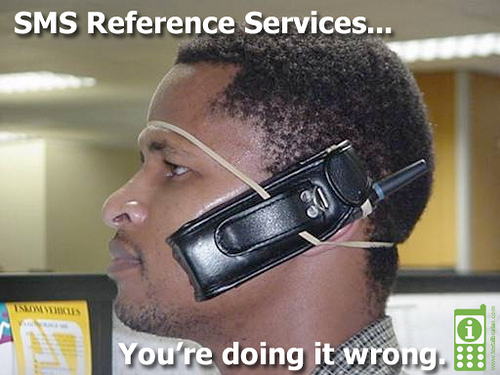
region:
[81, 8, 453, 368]
man has a cell phone on his head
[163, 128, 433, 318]
cell phone is color black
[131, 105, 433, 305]
cell phone hold by an elastic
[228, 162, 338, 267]
elastic over a phone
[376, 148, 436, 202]
antenna of phone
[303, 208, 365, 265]
an ear behind a phone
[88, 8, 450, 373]
man wears a squared shirt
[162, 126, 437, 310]
cell phone is in a case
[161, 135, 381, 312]
case of phone is black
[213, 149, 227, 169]
a rubber band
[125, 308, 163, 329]
hair on the mans face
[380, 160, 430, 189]
an antenna to the cellphone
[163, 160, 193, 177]
the mans left eye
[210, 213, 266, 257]
clip on the cellphone case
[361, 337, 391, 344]
the man is wearing a collar shirt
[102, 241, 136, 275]
the mans lips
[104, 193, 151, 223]
the mans nose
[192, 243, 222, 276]
a reflection of light on the case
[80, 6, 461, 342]
this is a person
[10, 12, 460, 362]
this is an advertisement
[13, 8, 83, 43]
a word on an advertisement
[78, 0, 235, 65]
a word on an advertisement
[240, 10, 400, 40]
a word on an advertisement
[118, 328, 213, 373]
a word on an advertisement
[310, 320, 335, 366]
a word on an advertisement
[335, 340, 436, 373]
a word on an advertisement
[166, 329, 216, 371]
a word on an advertisement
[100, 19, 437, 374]
Man with a cellphone strapped to his head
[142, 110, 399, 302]
Cell phone with rubber band strap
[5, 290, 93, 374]
Yellow paper with white logo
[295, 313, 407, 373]
Collar of a plaid shirt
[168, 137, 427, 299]
Cellphone in a leather case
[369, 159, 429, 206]
Antenna of a cellphone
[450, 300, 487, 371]
Green cellphone icon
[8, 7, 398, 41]
White typing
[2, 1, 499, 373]
Meme of SMS worker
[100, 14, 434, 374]
Man wearing a cellphone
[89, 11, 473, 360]
The head of the person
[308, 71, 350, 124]
Part of the hair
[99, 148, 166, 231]
The nose of the person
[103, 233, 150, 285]
The mouth of the person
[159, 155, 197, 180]
The left eye of the person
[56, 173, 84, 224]
Part of the wall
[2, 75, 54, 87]
Part of the light on the ceiling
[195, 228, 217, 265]
Part of the cellphone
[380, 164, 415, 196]
Part of the antenna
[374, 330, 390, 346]
Part of the shirt's collar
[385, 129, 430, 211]
antenna on the phone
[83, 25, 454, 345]
man has phone attached to head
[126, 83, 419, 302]
rubber band around head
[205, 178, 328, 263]
clip on the case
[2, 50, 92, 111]
light on the ceiling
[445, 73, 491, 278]
white trim on wall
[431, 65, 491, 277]
yellow wall on the side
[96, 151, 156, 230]
nose on the man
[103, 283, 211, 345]
beard of the man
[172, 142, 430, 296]
phone is strapped to head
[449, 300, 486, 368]
phone is green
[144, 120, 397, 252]
rubberband secures phone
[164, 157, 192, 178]
eye belongs to human